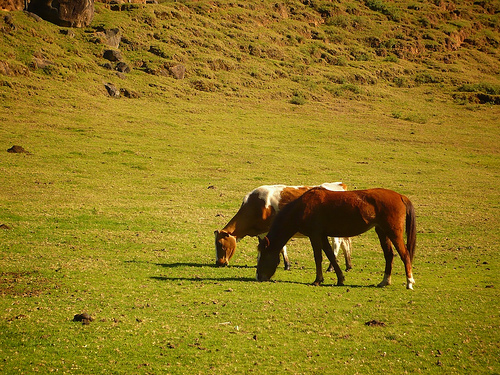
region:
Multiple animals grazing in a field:
[207, 173, 450, 308]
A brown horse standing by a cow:
[257, 182, 427, 302]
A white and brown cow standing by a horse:
[212, 180, 369, 268]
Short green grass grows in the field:
[35, 98, 466, 198]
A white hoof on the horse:
[400, 270, 422, 297]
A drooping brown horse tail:
[404, 202, 425, 253]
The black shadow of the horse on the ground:
[160, 268, 395, 298]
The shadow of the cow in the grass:
[156, 253, 261, 273]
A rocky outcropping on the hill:
[96, 30, 179, 96]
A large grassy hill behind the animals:
[54, 6, 440, 103]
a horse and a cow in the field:
[196, 151, 435, 302]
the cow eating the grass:
[202, 214, 243, 278]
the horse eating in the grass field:
[249, 229, 287, 284]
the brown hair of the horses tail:
[402, 191, 420, 260]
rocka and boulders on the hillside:
[25, 0, 185, 97]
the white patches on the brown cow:
[240, 181, 282, 213]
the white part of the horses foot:
[398, 265, 420, 298]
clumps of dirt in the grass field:
[68, 311, 95, 325]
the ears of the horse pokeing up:
[253, 231, 270, 248]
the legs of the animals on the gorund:
[281, 258, 414, 292]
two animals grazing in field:
[200, 149, 412, 301]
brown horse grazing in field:
[247, 190, 421, 285]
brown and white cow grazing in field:
[188, 186, 356, 270]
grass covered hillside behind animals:
[6, 4, 491, 97]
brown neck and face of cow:
[206, 197, 269, 262]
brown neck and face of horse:
[245, 219, 294, 280]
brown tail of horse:
[400, 204, 417, 262]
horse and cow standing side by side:
[202, 170, 421, 292]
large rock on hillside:
[30, 0, 107, 34]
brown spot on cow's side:
[275, 184, 320, 211]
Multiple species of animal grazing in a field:
[191, 162, 451, 307]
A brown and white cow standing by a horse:
[210, 182, 366, 267]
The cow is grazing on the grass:
[202, 220, 275, 270]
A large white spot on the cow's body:
[245, 180, 287, 210]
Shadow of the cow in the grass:
[162, 255, 262, 273]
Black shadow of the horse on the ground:
[150, 269, 379, 294]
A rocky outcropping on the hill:
[77, 25, 148, 104]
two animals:
[202, 173, 436, 284]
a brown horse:
[254, 185, 422, 278]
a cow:
[200, 220, 246, 263]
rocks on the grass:
[68, 300, 107, 330]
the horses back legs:
[370, 233, 420, 290]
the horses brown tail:
[403, 204, 418, 249]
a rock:
[7, 135, 31, 155]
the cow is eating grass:
[205, 227, 240, 272]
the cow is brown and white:
[240, 176, 286, 202]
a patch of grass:
[460, 78, 497, 95]